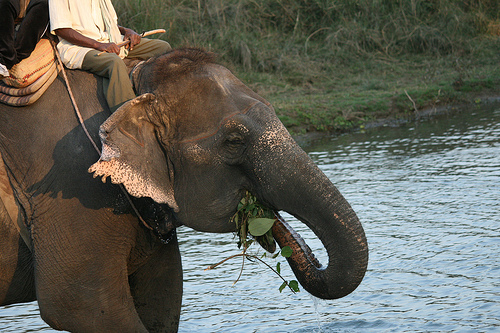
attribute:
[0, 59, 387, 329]
elephant — walking, eating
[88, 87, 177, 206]
ear — gray, cut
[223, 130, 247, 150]
eye — closed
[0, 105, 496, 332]
water — calm, clear, green, flat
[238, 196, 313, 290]
weeds — green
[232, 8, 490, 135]
shore — weedy